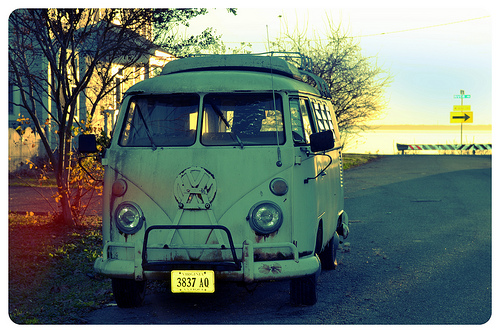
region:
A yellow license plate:
[167, 264, 218, 297]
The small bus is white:
[91, 48, 352, 307]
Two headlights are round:
[111, 199, 282, 242]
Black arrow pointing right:
[449, 107, 471, 127]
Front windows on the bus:
[111, 87, 291, 152]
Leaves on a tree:
[276, 28, 388, 138]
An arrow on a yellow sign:
[447, 104, 475, 127]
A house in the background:
[9, 7, 177, 159]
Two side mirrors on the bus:
[64, 124, 340, 186]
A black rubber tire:
[285, 272, 320, 310]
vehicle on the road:
[83, 53, 364, 302]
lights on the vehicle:
[110, 175, 302, 242]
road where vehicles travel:
[363, 163, 482, 310]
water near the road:
[351, 128, 493, 148]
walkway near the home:
[11, 184, 98, 216]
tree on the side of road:
[11, 10, 217, 239]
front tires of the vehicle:
[100, 270, 331, 309]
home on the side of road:
[15, 8, 177, 136]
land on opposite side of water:
[368, 116, 497, 128]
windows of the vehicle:
[126, 95, 279, 150]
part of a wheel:
[307, 283, 321, 294]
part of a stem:
[63, 189, 83, 200]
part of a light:
[276, 211, 296, 221]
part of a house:
[81, 65, 98, 85]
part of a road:
[403, 142, 413, 157]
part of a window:
[261, 117, 267, 126]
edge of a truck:
[186, 258, 193, 269]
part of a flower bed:
[63, 252, 85, 270]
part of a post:
[458, 114, 464, 119]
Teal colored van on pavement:
[100, 37, 338, 293]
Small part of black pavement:
[437, 257, 467, 308]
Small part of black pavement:
[386, 257, 435, 313]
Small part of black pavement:
[335, 274, 342, 292]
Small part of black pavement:
[249, 297, 324, 332]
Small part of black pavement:
[354, 231, 404, 303]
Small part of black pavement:
[406, 212, 453, 279]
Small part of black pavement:
[450, 200, 495, 285]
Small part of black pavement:
[361, 180, 418, 234]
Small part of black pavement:
[432, 174, 486, 241]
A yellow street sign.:
[450, 111, 473, 119]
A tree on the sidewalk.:
[9, 8, 206, 218]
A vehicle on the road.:
[92, 53, 348, 312]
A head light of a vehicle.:
[114, 203, 143, 228]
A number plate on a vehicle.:
[171, 269, 216, 293]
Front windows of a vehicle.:
[117, 92, 284, 147]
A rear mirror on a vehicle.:
[304, 130, 334, 153]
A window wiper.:
[132, 95, 158, 148]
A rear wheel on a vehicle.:
[320, 215, 342, 267]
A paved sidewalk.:
[12, 155, 103, 315]